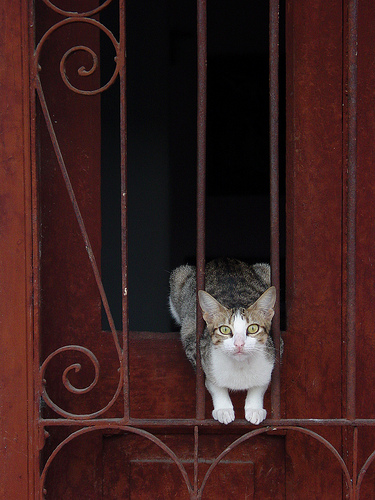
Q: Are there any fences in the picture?
A: No, there are no fences.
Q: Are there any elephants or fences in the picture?
A: No, there are no fences or elephants.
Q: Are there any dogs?
A: No, there are no dogs.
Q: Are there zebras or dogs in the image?
A: No, there are no dogs or zebras.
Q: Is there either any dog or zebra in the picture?
A: No, there are no dogs or zebras.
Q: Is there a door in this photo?
A: Yes, there is a door.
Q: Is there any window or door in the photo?
A: Yes, there is a door.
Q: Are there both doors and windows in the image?
A: Yes, there are both a door and a window.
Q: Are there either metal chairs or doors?
A: Yes, there is a metal door.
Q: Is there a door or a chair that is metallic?
A: Yes, the door is metallic.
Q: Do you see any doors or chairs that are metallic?
A: Yes, the door is metallic.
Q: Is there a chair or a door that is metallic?
A: Yes, the door is metallic.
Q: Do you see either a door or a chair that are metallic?
A: Yes, the door is metallic.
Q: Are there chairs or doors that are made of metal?
A: Yes, the door is made of metal.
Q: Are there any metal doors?
A: Yes, there is a door that is made of metal.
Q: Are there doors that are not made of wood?
A: Yes, there is a door that is made of metal.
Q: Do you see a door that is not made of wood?
A: Yes, there is a door that is made of metal.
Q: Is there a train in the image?
A: No, there are no trains.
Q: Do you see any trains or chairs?
A: No, there are no trains or chairs.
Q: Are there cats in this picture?
A: Yes, there is a cat.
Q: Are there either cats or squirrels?
A: Yes, there is a cat.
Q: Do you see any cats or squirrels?
A: Yes, there is a cat.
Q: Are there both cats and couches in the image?
A: No, there is a cat but no couches.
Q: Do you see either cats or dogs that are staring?
A: Yes, the cat is staring.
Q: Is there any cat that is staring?
A: Yes, there is a cat that is staring.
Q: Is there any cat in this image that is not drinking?
A: Yes, there is a cat that is staring.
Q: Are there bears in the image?
A: No, there are no bears.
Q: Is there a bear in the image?
A: No, there are no bears.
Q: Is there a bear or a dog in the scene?
A: No, there are no bears or dogs.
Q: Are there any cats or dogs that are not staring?
A: No, there is a cat but it is staring.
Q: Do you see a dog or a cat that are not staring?
A: No, there is a cat but it is staring.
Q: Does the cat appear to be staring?
A: Yes, the cat is staring.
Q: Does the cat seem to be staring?
A: Yes, the cat is staring.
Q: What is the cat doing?
A: The cat is staring.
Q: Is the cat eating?
A: No, the cat is staring.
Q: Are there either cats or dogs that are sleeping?
A: No, there is a cat but it is staring.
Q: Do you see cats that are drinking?
A: No, there is a cat but it is staring.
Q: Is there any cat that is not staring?
A: No, there is a cat but it is staring.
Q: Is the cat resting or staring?
A: The cat is staring.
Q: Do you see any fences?
A: No, there are no fences.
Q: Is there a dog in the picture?
A: No, there are no dogs.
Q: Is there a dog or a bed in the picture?
A: No, there are no dogs or beds.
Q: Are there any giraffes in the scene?
A: No, there are no giraffes.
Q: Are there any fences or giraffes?
A: No, there are no giraffes or fences.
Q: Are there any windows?
A: Yes, there is a window.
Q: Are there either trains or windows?
A: Yes, there is a window.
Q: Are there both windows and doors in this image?
A: Yes, there are both a window and a door.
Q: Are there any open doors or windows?
A: Yes, there is an open window.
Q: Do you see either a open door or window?
A: Yes, there is an open window.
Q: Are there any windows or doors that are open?
A: Yes, the window is open.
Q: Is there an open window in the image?
A: Yes, there is an open window.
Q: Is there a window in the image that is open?
A: Yes, there is a window that is open.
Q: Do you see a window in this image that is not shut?
A: Yes, there is a open window.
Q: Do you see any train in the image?
A: No, there are no trains.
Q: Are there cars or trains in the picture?
A: No, there are no trains or cars.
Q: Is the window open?
A: Yes, the window is open.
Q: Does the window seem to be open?
A: Yes, the window is open.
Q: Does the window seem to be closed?
A: No, the window is open.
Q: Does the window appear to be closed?
A: No, the window is open.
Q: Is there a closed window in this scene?
A: No, there is a window but it is open.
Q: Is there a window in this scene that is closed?
A: No, there is a window but it is open.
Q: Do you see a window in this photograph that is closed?
A: No, there is a window but it is open.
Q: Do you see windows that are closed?
A: No, there is a window but it is open.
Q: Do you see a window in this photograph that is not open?
A: No, there is a window but it is open.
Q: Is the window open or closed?
A: The window is open.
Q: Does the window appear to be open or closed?
A: The window is open.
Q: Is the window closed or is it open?
A: The window is open.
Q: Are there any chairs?
A: No, there are no chairs.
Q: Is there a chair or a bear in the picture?
A: No, there are no chairs or bears.